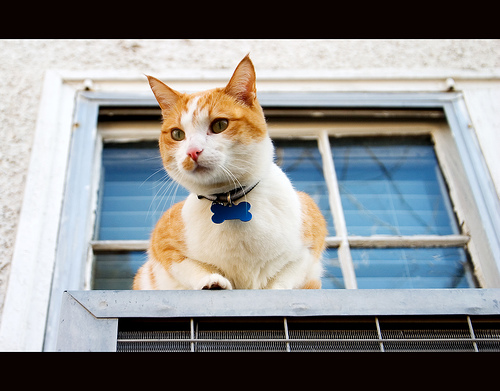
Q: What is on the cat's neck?
A: Collar.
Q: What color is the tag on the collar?
A: Blue.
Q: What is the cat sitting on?
A: Air conditioner unit.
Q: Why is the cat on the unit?
A: Resting.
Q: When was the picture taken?
A: Daytime.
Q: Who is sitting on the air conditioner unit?
A: Cat.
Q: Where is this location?
A: Outside a window.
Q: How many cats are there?
A: One.